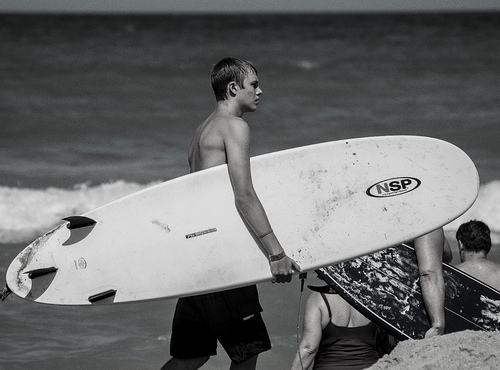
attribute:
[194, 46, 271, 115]
guy — shirtless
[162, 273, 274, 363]
shorts — black